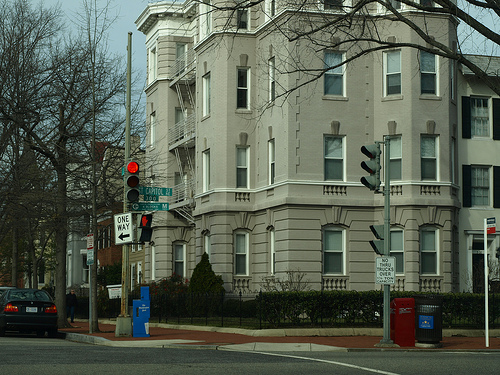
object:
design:
[132, 0, 202, 34]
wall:
[287, 13, 377, 186]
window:
[317, 222, 344, 273]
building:
[135, 0, 498, 302]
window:
[384, 132, 404, 183]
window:
[471, 166, 493, 212]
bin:
[413, 295, 444, 346]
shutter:
[461, 163, 474, 206]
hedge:
[261, 290, 500, 329]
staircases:
[169, 37, 200, 212]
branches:
[226, 36, 440, 128]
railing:
[79, 287, 500, 330]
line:
[244, 346, 397, 373]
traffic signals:
[357, 135, 384, 194]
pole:
[379, 130, 397, 344]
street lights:
[357, 134, 389, 254]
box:
[130, 277, 157, 338]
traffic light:
[122, 154, 143, 210]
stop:
[122, 157, 140, 177]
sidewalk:
[59, 320, 500, 352]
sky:
[0, 0, 500, 193]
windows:
[228, 225, 256, 280]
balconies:
[163, 133, 203, 212]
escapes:
[164, 67, 195, 152]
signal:
[122, 155, 143, 176]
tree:
[0, 0, 176, 338]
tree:
[182, 246, 228, 318]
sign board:
[113, 211, 136, 247]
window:
[318, 127, 349, 182]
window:
[318, 46, 349, 102]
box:
[390, 297, 414, 350]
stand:
[417, 302, 443, 344]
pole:
[115, 29, 132, 341]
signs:
[127, 200, 172, 214]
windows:
[232, 141, 253, 193]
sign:
[112, 211, 137, 246]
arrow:
[115, 232, 129, 240]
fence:
[158, 288, 261, 329]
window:
[469, 92, 494, 139]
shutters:
[462, 96, 474, 139]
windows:
[266, 136, 278, 188]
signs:
[136, 185, 176, 198]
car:
[0, 283, 61, 341]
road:
[0, 338, 500, 373]